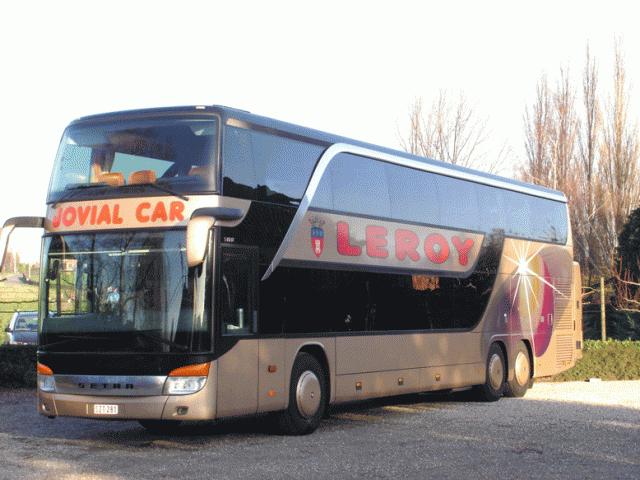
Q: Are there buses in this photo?
A: Yes, there is a bus.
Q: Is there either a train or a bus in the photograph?
A: Yes, there is a bus.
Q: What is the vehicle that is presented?
A: The vehicle is a bus.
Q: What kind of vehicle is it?
A: The vehicle is a bus.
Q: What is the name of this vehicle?
A: This is a bus.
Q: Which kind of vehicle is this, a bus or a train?
A: This is a bus.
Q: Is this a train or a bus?
A: This is a bus.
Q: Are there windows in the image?
A: Yes, there is a window.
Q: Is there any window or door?
A: Yes, there is a window.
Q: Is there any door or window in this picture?
A: Yes, there is a window.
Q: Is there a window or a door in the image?
A: Yes, there is a window.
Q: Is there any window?
A: Yes, there is a window.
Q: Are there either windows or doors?
A: Yes, there is a window.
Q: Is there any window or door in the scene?
A: Yes, there is a window.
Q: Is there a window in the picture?
A: Yes, there is a window.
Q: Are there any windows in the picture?
A: Yes, there is a window.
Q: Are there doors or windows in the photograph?
A: Yes, there is a window.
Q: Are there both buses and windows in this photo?
A: Yes, there are both a window and a bus.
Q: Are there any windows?
A: Yes, there is a window.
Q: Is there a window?
A: Yes, there is a window.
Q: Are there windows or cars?
A: Yes, there is a window.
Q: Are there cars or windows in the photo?
A: Yes, there is a window.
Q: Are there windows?
A: Yes, there is a window.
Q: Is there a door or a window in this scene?
A: Yes, there is a window.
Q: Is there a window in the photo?
A: Yes, there is a window.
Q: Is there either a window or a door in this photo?
A: Yes, there is a window.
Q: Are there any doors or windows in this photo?
A: Yes, there is a window.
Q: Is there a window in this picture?
A: Yes, there is a window.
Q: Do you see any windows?
A: Yes, there is a window.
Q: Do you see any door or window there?
A: Yes, there is a window.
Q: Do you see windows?
A: Yes, there is a window.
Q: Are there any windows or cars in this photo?
A: Yes, there is a window.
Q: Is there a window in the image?
A: Yes, there is a window.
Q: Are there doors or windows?
A: Yes, there is a window.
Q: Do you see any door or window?
A: Yes, there is a window.